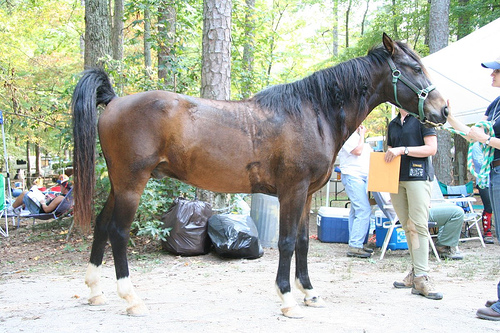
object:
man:
[366, 107, 442, 305]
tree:
[374, 0, 500, 188]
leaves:
[175, 17, 194, 50]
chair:
[0, 186, 76, 230]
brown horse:
[69, 32, 449, 319]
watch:
[485, 136, 493, 146]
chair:
[364, 180, 497, 261]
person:
[426, 192, 465, 259]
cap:
[479, 58, 499, 70]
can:
[248, 192, 281, 249]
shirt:
[385, 112, 437, 182]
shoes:
[393, 270, 443, 300]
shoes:
[476, 300, 499, 322]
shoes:
[432, 241, 465, 259]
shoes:
[483, 235, 494, 244]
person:
[474, 178, 493, 245]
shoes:
[345, 246, 373, 257]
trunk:
[314, 205, 371, 244]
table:
[327, 163, 352, 208]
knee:
[278, 235, 297, 259]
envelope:
[367, 152, 400, 194]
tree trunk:
[200, 0, 233, 101]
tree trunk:
[83, 0, 110, 68]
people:
[339, 114, 375, 258]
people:
[446, 59, 499, 321]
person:
[384, 107, 444, 300]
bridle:
[381, 52, 452, 128]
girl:
[438, 57, 499, 322]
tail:
[68, 67, 117, 237]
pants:
[389, 181, 431, 281]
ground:
[0, 178, 500, 333]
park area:
[0, 137, 188, 269]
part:
[280, 304, 306, 318]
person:
[0, 180, 72, 221]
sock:
[482, 210, 491, 237]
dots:
[483, 215, 489, 228]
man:
[427, 202, 466, 260]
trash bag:
[206, 213, 265, 259]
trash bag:
[160, 196, 213, 256]